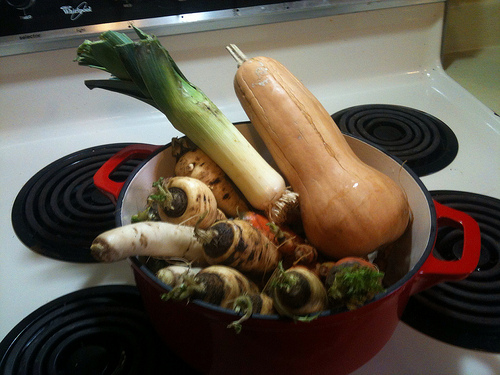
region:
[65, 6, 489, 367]
vegetables in a pot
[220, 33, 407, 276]
a squash over a pot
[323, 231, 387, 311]
a carrot in a pot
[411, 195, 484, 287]
a handle on the right side of pot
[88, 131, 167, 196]
a handle on the left side of pot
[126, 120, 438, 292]
red pot is white inside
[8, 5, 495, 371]
a red pot on stove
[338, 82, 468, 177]
black burner on stove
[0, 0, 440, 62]
stove has metal border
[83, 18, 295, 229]
a green and white vegetable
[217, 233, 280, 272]
vegetable in the pot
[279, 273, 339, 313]
vegetable in the pot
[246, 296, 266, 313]
vegetable in the pot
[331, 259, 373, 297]
vegetable in the pot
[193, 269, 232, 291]
vegetable in the pot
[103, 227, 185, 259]
vegetable in the pot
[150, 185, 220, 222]
vegetable in the pot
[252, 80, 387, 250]
vegetable in the pot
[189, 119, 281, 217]
vegetable in the pot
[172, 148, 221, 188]
vegetable in the pot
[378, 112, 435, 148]
a black burner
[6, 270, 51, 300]
the stove is white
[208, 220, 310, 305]
veggies in a pot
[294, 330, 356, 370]
the pot is red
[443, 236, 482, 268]
the handle of the pot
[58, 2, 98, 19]
logo on the stove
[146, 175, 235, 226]
turnips in the pot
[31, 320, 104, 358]
a black burner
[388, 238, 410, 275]
a shadow in the pot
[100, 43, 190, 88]
a green stem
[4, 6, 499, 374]
Vegetables on a stove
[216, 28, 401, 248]
a squash in a pot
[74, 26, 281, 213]
a leek in a pot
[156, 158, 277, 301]
turnips in a pot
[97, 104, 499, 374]
A large red pot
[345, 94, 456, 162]
a small burner on a stove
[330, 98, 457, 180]
an electric burner on a stove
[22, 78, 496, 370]
an electric stove top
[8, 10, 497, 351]
a white stove with black burners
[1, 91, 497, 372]
a four burner stove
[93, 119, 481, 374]
An orange cooking pot.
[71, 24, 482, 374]
Veggies in a pot.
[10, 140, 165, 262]
A burner on a stove.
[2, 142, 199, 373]
Two burners on a stove.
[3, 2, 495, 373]
A white stove top.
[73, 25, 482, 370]
A pot of veggies.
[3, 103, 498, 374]
Four burners on a stove.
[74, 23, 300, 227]
A green and white vegetable.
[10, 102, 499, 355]
Three burners on a stove.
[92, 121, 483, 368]
A pot on a stove.